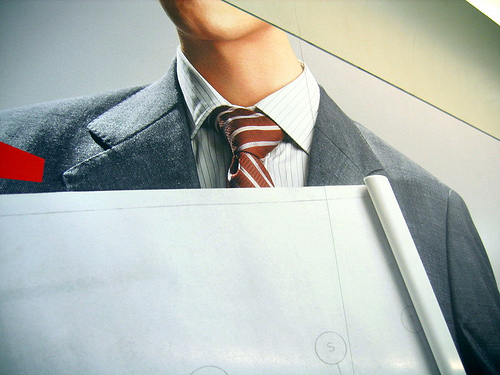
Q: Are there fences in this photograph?
A: No, there are no fences.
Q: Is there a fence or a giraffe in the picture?
A: No, there are no fences or giraffes.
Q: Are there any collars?
A: Yes, there is a collar.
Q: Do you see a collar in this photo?
A: Yes, there is a collar.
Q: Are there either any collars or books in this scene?
A: Yes, there is a collar.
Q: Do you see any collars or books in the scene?
A: Yes, there is a collar.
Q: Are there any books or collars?
A: Yes, there is a collar.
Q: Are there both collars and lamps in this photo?
A: No, there is a collar but no lamps.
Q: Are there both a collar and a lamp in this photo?
A: No, there is a collar but no lamps.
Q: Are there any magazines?
A: No, there are no magazines.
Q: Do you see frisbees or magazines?
A: No, there are no magazines or frisbees.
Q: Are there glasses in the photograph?
A: No, there are no glasses.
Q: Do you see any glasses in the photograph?
A: No, there are no glasses.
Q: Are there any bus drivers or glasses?
A: No, there are no glasses or bus drivers.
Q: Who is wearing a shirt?
A: The man is wearing a shirt.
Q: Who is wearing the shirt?
A: The man is wearing a shirt.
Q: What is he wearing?
A: The man is wearing a shirt.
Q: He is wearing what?
A: The man is wearing a shirt.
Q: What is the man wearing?
A: The man is wearing a shirt.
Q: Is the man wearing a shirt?
A: Yes, the man is wearing a shirt.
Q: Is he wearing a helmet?
A: No, the man is wearing a shirt.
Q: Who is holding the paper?
A: The man is holding the paper.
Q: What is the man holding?
A: The man is holding the paper.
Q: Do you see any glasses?
A: No, there are no glasses.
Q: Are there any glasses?
A: No, there are no glasses.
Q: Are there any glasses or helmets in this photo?
A: No, there are no glasses or helmets.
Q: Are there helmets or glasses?
A: No, there are no glasses or helmets.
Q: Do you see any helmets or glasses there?
A: No, there are no glasses or helmets.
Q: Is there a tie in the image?
A: Yes, there is a tie.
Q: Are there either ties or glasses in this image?
A: Yes, there is a tie.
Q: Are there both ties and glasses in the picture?
A: No, there is a tie but no glasses.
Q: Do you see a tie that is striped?
A: Yes, there is a striped tie.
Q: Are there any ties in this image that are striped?
A: Yes, there is a tie that is striped.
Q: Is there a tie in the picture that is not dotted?
A: Yes, there is a striped tie.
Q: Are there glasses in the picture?
A: No, there are no glasses.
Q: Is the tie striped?
A: Yes, the tie is striped.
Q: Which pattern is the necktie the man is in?
A: The tie is striped.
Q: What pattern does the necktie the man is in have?
A: The tie has striped pattern.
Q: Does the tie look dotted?
A: No, the tie is striped.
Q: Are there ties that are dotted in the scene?
A: No, there is a tie but it is striped.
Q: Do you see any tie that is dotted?
A: No, there is a tie but it is striped.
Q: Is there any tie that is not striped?
A: No, there is a tie but it is striped.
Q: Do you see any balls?
A: No, there are no balls.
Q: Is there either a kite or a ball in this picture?
A: No, there are no balls or kites.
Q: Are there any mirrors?
A: No, there are no mirrors.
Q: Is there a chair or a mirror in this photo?
A: No, there are no mirrors or chairs.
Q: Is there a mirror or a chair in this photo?
A: No, there are no mirrors or chairs.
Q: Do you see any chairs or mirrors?
A: No, there are no mirrors or chairs.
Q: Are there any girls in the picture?
A: No, there are no girls.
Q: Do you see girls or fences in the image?
A: No, there are no girls or fences.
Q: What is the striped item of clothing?
A: The clothing item is a shirt.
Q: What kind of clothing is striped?
A: The clothing is a shirt.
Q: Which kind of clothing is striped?
A: The clothing is a shirt.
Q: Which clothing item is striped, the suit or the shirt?
A: The shirt is striped.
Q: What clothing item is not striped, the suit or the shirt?
A: The suit is not striped.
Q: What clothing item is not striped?
A: The clothing item is a suit.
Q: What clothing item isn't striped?
A: The clothing item is a suit.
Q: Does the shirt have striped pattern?
A: Yes, the shirt is striped.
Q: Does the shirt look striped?
A: Yes, the shirt is striped.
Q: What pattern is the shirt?
A: The shirt is striped.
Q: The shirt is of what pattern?
A: The shirt is striped.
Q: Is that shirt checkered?
A: No, the shirt is striped.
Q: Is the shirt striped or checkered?
A: The shirt is striped.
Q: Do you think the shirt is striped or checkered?
A: The shirt is striped.